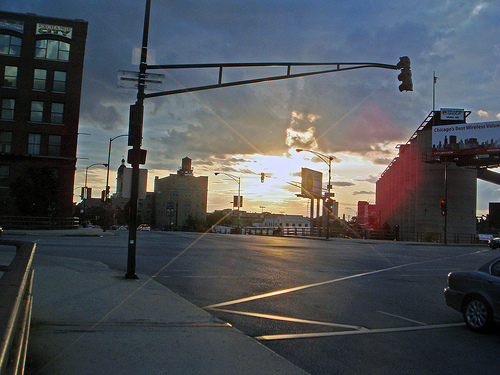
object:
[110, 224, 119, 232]
cars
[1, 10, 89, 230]
buildng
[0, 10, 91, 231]
front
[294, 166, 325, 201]
billboard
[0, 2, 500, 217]
sky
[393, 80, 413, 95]
light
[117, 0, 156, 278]
pole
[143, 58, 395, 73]
arm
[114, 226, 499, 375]
street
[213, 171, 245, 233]
lightposts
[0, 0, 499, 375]
background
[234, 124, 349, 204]
sun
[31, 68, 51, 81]
windows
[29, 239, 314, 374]
sidewalk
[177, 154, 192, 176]
tower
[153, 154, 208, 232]
building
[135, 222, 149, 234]
car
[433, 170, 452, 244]
traffic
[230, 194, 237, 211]
sign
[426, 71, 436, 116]
pole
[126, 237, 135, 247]
button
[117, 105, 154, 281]
support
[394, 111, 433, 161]
rail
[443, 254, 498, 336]
vehicle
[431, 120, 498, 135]
text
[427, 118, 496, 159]
sign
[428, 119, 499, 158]
print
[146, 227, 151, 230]
lights